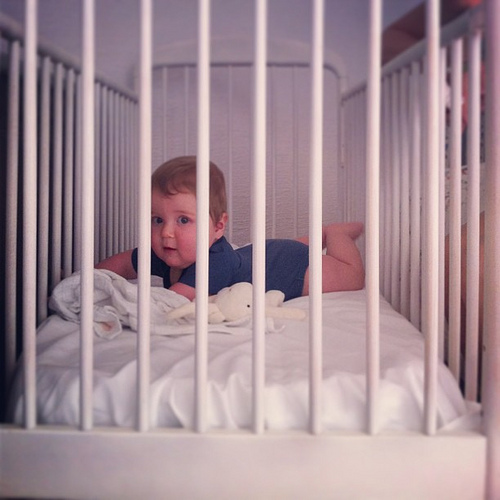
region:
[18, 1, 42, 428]
white rail on baby bed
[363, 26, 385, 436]
white rail on baby bed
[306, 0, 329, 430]
white rail on baby bed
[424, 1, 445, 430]
white rail on baby bed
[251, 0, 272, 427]
white rail on baby bed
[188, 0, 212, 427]
white rail on baby bed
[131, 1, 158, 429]
white rail on baby bed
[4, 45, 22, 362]
white rail on baby bed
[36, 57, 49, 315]
white rail on baby bed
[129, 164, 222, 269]
face of the baby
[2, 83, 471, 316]
baby in the crib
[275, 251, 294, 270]
the onesie is blue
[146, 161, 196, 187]
hair of the baby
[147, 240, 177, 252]
mouth of the baby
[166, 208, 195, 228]
eye of te baby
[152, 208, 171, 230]
eye of the baby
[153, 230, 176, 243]
nose of the baby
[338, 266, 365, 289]
knee of the baby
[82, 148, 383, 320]
chubby baby boy laying on tummy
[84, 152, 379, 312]
baby boy wearing blue romper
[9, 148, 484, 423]
baby boy laying on white rumpled crib sheets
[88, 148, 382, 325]
baby boy with blond hair and blue eyes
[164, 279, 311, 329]
small white stuffed rabbit toy next to boy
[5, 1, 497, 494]
small white crib with tall barred sides holding baby boy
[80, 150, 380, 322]
white baby boy laying on stomach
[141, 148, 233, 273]
baby boy with round chubby face, blue eyes and blond hair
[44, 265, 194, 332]
white knitted baby blanket in front of baby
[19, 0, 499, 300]
white walls behind white crib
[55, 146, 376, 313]
A baby in a crib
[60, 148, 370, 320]
A baby in a crib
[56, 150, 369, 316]
A baby in a crib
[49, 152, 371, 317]
A baby in a crib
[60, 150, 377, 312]
A baby in a crib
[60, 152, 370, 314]
A baby in a crib